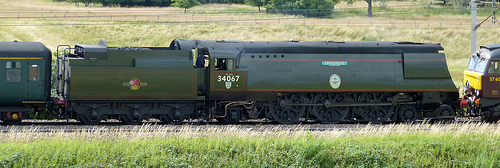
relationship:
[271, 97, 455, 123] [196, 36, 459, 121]
metal wheel on train engine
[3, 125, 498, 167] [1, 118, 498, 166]
tall grass on field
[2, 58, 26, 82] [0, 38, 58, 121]
window on car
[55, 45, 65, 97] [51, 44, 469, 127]
ladder on back of train car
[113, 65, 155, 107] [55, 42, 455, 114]
logo on car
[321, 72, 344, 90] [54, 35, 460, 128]
design on side of car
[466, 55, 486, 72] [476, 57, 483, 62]
windshield has wiper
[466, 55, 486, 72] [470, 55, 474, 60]
windshield has wiper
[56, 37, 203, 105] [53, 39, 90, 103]
car has end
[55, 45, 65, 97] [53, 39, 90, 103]
ladder on end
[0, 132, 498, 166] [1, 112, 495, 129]
grass near railroad line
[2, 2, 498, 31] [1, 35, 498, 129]
fence on other side of train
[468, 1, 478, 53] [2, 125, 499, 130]
pole beside train track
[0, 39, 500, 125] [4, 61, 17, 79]
train has window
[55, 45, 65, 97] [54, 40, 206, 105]
ladder on train car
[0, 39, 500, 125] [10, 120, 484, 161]
train in field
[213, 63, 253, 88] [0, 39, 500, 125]
number on train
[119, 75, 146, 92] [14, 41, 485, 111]
emblem on side of train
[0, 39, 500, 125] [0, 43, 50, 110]
train has car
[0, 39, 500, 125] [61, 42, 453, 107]
train has car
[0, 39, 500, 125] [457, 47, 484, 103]
train has car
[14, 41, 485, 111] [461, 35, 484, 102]
train has car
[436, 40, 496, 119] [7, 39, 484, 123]
pole near railroad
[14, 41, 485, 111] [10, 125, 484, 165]
train passing in field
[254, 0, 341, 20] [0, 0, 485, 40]
trees on field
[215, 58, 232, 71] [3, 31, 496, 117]
person in train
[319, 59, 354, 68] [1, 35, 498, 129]
text on train